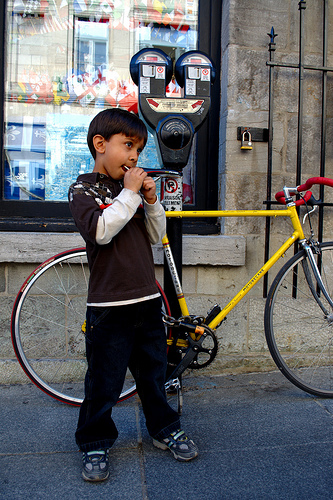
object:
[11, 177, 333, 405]
bike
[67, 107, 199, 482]
boy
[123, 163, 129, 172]
sucker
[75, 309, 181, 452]
pants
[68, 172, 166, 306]
shirt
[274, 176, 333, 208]
handles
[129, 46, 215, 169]
parking meter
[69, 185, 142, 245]
sleeves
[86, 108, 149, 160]
hair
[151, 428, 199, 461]
shoe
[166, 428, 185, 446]
velcro strap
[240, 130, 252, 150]
padlock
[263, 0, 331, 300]
gate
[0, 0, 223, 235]
window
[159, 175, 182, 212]
no parking sticker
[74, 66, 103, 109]
flag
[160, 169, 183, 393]
pole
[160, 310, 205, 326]
security chain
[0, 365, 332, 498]
sidewalk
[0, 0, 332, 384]
buiding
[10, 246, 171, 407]
wheel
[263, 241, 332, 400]
wheel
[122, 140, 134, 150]
eye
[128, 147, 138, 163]
nose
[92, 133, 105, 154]
ear